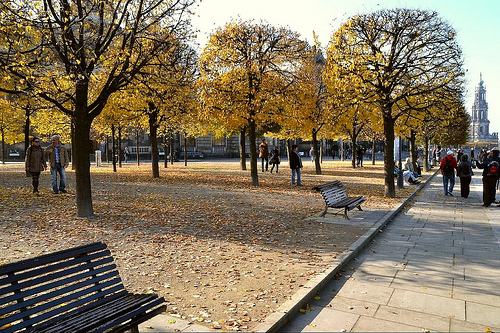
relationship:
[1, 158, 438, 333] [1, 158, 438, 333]
leaf on ground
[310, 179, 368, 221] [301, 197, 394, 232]
bench on base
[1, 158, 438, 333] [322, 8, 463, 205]
leaf on leaf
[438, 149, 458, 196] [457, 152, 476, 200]
man with person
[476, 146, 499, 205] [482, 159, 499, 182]
person with backpack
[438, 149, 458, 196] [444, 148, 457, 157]
man wearing hat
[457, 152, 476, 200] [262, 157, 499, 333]
person on street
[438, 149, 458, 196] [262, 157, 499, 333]
man on street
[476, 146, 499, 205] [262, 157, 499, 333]
person on street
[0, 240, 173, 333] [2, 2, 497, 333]
bench in park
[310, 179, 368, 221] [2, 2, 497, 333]
bench in park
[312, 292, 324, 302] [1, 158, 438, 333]
leaf in group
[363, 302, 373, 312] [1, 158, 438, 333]
leaf in group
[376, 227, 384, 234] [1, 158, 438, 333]
leaf in group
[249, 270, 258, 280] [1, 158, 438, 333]
leaf in group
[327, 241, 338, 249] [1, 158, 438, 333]
leaf in group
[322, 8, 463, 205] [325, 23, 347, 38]
tree has leaf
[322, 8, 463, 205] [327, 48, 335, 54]
tree has leaf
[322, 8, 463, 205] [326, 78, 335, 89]
tree has leaf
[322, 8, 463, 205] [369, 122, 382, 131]
tree has leaf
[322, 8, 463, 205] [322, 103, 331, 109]
tree has leaf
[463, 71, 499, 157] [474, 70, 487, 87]
building has top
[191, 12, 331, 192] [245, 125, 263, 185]
tree has trunk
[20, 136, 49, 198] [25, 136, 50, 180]
wife has jacket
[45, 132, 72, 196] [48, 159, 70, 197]
man has pants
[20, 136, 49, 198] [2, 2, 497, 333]
wife in park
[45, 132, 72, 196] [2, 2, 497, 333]
person in park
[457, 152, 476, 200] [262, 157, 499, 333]
person on sidewalk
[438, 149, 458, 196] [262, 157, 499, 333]
man on sidewalk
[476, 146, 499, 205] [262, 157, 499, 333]
person on sidewalk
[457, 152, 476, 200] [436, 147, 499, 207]
person in group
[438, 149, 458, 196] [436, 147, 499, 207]
man in group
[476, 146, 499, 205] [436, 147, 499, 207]
person in group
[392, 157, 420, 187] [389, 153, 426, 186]
person in group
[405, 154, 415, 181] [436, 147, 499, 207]
person in group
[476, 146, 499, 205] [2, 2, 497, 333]
person in park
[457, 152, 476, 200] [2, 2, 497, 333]
person in park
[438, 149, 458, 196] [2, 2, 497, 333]
man in park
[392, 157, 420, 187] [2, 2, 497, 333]
person in park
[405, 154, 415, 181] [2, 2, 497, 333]
person in park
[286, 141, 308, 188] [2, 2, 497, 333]
person in park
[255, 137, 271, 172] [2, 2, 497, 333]
person in park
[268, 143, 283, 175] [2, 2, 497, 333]
person in park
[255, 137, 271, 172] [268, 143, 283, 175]
man with girl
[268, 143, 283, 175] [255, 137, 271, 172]
girl with man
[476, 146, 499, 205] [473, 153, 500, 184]
man wearing jacket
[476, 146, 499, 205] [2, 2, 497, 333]
man in park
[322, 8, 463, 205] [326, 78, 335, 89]
tree with leaf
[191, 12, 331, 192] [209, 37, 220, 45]
tree with leaf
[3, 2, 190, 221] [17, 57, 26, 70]
tree with leaf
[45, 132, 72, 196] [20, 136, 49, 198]
person with wife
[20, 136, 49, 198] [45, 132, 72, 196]
wife with person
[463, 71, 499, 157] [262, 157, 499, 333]
building on path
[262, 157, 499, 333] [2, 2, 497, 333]
path in park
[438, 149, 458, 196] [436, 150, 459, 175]
man in shirt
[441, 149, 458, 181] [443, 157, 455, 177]
man has backpack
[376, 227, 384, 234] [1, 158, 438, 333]
leaf on ground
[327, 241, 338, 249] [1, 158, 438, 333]
leaf on ground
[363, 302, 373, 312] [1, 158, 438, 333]
leaf on ground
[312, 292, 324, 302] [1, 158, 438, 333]
leaf on ground